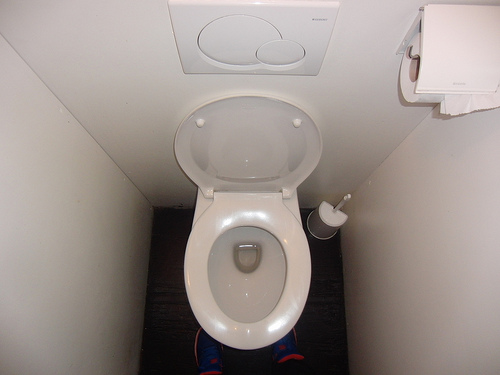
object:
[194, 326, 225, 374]
shoe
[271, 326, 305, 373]
shoe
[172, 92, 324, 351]
toilet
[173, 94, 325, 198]
lid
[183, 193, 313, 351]
seat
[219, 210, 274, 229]
reflection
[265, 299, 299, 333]
reflection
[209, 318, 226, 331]
reflection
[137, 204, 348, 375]
floor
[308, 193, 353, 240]
toilet brush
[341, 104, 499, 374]
wall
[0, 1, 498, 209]
wall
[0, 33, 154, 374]
wall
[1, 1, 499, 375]
scene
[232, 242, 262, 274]
water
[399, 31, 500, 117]
toilet paper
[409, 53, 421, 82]
roll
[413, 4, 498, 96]
cover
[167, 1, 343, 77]
panel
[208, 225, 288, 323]
bowl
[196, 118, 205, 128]
stopper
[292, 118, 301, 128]
stopper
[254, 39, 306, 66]
button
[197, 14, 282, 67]
button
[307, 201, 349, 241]
container